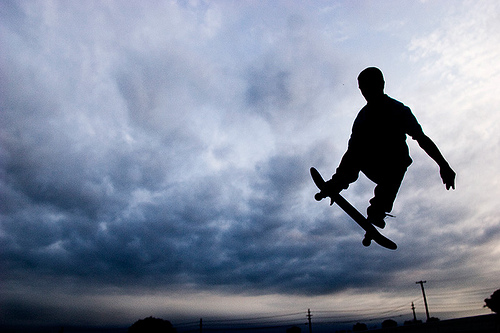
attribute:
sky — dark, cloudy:
[23, 0, 484, 307]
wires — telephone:
[189, 284, 498, 331]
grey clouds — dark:
[0, 137, 487, 292]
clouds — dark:
[2, 2, 498, 297]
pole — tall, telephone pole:
[395, 270, 450, 323]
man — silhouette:
[316, 48, 450, 266]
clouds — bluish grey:
[82, 114, 237, 251]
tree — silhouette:
[126, 303, 181, 330]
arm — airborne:
[405, 106, 460, 194]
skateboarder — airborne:
[321, 67, 453, 230]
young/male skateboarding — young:
[297, 46, 467, 259]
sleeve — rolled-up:
[329, 102, 364, 157]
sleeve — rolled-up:
[390, 102, 440, 156]